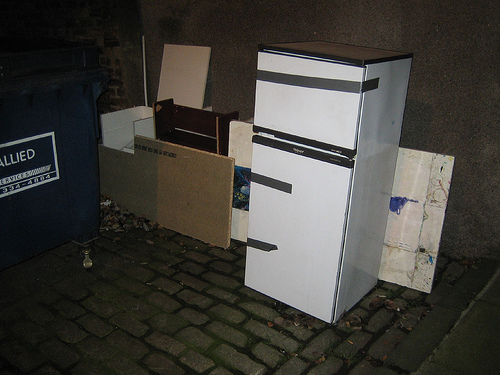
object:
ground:
[0, 199, 499, 374]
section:
[266, 326, 402, 373]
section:
[401, 295, 499, 372]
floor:
[0, 196, 468, 374]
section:
[95, 244, 258, 345]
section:
[35, 228, 266, 375]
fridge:
[243, 38, 415, 325]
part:
[244, 213, 388, 289]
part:
[244, 123, 402, 256]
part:
[251, 39, 412, 149]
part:
[244, 235, 386, 325]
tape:
[255, 69, 380, 94]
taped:
[250, 171, 293, 195]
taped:
[246, 236, 278, 252]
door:
[242, 51, 365, 325]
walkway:
[13, 253, 342, 371]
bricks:
[0, 222, 338, 374]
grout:
[252, 335, 262, 340]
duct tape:
[258, 132, 275, 138]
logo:
[0, 130, 61, 199]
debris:
[97, 198, 163, 234]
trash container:
[0, 80, 104, 272]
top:
[259, 40, 414, 65]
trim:
[257, 40, 413, 64]